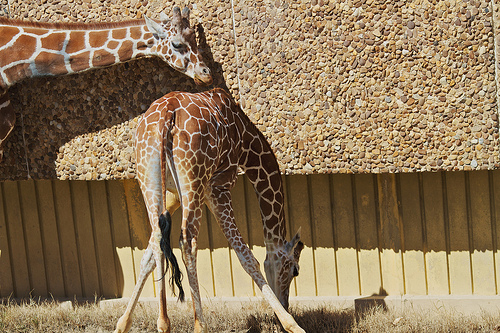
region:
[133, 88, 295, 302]
A young giraffe learnig to stand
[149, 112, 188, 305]
The giraffe has black hair on its tail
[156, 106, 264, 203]
The giraffe is brown and white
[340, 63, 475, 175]
The building has small rocks all over it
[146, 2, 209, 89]
The giraffe looks like its blowing kisses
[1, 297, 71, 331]
The grass looks very dry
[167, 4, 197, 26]
Horns on a giraffes head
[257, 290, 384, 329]
Shadow of a giraffe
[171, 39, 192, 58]
The eye of a giraffe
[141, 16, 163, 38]
Ear of a giraffe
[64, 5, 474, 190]
brown pebbled wall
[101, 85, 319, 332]
young giraffe standing on wobbly legs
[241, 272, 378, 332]
shadow cast by a giraffe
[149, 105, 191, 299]
long tail with black hair on the end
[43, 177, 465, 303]
dirty yellow siding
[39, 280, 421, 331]
grass that is dead and brown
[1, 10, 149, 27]
short light brown mane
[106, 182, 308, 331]
giraffes legs going sideways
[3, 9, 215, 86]
large giraffe with its head extended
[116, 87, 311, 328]
giraffe with its nose to the ground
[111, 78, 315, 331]
baby giraffe trying to stand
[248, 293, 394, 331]
shadow of baby giraffe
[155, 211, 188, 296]
black tail of baby giraffe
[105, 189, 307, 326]
splayed front legs of baby girafe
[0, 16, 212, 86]
giraffe leaning against wall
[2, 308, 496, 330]
dried grass against wall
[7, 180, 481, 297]
shadow of rock wall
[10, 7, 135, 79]
neck of giraffe against wall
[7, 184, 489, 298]
wood panel wall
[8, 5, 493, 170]
tiny rocks in top of wall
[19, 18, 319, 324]
Two giraffes zoo compound.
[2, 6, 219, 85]
Larger giraffe other side fence.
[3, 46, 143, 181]
Shadow of giraffe against wall.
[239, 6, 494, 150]
Wall made of tan gravel stones.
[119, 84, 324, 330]
Smaller baby giraffe this side fence.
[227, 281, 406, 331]
Dark shadow small giraffe field.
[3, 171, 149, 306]
Wood slats make up fencing.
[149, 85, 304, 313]
Bent over looking for food.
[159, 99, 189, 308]
Skinny tail ends dark swatch hair.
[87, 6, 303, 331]
Mother giraffe overlooking child.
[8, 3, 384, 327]
two brown and white spotted giraffes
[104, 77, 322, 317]
giraffe eating grass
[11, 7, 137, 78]
neck of a giraffe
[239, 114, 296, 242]
neck of a giraffe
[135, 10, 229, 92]
head of a giraffe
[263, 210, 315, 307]
head of a giraffe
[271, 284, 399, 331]
shadow of a giraffe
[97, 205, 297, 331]
four legs of a giraffe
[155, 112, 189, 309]
tail of a giraffe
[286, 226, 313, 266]
ears of a giraffe